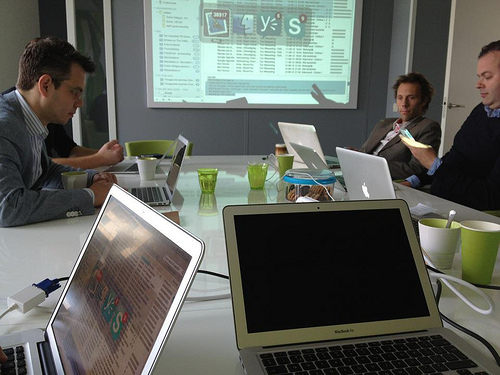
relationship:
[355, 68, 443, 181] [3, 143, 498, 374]
man sitting table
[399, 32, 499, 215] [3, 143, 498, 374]
man sitting table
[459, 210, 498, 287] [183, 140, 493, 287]
green cup on table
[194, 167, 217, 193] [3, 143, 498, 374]
glass on table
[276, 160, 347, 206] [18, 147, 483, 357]
container on table table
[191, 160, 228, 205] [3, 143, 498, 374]
glass on table table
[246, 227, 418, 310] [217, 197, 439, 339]
screen of laptop laptop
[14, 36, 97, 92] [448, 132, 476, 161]
brown hair on  man ground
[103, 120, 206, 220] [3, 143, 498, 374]
laptop on table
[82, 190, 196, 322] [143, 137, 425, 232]
laptop on table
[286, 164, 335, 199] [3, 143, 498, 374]
bowl on table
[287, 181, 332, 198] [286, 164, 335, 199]
cookies are in bowl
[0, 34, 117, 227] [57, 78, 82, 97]
man wearing glasses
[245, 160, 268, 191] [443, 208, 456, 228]
glass has utensil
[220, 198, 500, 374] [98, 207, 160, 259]
laptop has reflection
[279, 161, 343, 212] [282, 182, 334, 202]
tupperware has cookies